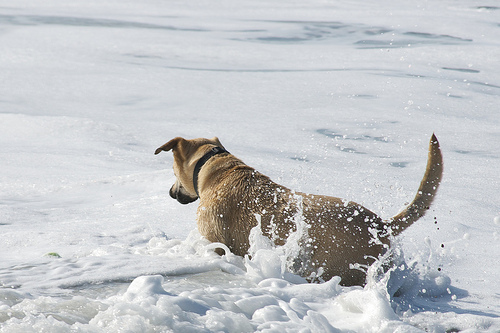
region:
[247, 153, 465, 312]
wet white snow flying up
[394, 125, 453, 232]
a dog's brown tail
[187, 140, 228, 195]
a black dog collar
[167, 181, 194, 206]
black snout of a brown dog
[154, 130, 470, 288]
a brown dog in the snow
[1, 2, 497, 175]
tracks in the snow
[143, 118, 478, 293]
a dog standing deep in the snow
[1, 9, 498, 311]
a dog jumping around in the white snow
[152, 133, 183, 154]
a dog ear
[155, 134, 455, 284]
matted wet dog fur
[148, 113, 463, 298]
brown dog in water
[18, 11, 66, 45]
white clouds in blue sky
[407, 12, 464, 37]
white clouds in blue sky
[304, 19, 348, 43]
white clouds in blue sky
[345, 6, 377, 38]
white clouds in blue sky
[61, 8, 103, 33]
white clouds in blue sky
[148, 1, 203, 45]
white clouds in blue sky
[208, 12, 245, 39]
white clouds in blue sky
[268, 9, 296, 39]
white clouds in blue sky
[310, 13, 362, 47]
white clouds in blue sky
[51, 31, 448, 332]
dog playing in water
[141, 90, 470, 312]
a big yellow dog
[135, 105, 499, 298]
a big yellow dog with a black collar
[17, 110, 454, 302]
a green tennis ball in the water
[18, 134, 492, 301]
dog fetching ball from water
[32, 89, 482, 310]
yellow dog fetching the green ball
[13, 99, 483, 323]
yellow dog retrieving a green ball from water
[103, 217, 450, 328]
water splashing up from dog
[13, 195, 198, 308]
a green toy the dog is after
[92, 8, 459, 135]
spots in a lake that is defrosted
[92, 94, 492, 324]
the dog is wading in the surf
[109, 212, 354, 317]
the foam on the waves is white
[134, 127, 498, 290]
the dog is brown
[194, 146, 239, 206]
the dog's collar is black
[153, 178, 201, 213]
the dog's muzzle is black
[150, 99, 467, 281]
the dog in the shallow surf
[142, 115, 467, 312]
the dog appears to be watching something in the water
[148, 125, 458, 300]
the dog is churning the water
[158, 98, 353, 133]
the water appears pretty calm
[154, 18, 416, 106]
the water is calm & blue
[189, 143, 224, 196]
a black nylon colar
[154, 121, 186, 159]
ears are floppy on the dog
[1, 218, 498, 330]
water is foamy near the shore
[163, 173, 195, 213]
the front of the muzzle has black fur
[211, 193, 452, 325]
the dog splashes in the water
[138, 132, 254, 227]
dog stares down at the moving water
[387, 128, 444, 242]
tail stands up at attention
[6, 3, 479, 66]
a swirl of water farther out from shore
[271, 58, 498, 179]
ripples in the foamy water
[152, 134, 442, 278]
a medium sized dog with a yellow coat